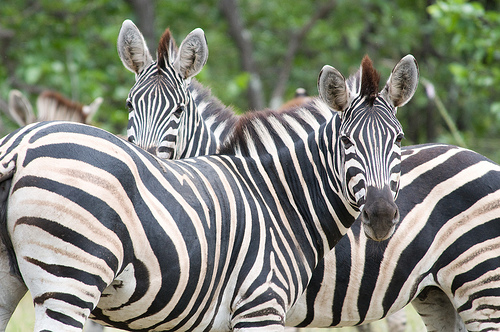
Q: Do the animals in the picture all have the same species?
A: Yes, all the animals are zebras.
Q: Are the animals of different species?
A: No, all the animals are zebras.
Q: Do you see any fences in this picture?
A: No, there are no fences.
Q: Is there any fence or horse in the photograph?
A: No, there are no fences or horses.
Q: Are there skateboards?
A: No, there are no skateboards.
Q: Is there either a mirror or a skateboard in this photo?
A: No, there are no skateboards or mirrors.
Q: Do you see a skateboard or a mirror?
A: No, there are no skateboards or mirrors.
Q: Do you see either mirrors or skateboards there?
A: No, there are no skateboards or mirrors.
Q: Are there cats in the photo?
A: No, there are no cats.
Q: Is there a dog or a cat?
A: No, there are no cats or dogs.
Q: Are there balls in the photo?
A: No, there are no balls.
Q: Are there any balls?
A: No, there are no balls.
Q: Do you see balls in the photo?
A: No, there are no balls.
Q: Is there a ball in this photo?
A: No, there are no balls.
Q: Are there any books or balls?
A: No, there are no balls or books.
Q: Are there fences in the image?
A: No, there are no fences.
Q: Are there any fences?
A: No, there are no fences.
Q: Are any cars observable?
A: No, there are no cars.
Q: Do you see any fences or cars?
A: No, there are no cars or fences.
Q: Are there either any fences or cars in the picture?
A: No, there are no cars or fences.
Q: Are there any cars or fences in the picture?
A: No, there are no cars or fences.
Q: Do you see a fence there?
A: No, there are no fences.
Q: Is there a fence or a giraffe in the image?
A: No, there are no fences or giraffes.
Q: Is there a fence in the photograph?
A: No, there are no fences.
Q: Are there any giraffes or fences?
A: No, there are no fences or giraffes.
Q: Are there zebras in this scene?
A: Yes, there is a zebra.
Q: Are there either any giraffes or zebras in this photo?
A: Yes, there is a zebra.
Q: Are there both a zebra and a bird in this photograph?
A: No, there is a zebra but no birds.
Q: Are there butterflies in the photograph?
A: No, there are no butterflies.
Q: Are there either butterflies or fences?
A: No, there are no butterflies or fences.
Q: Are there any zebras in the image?
A: Yes, there is a zebra.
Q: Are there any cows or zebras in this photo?
A: Yes, there is a zebra.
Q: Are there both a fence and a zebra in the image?
A: No, there is a zebra but no fences.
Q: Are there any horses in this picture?
A: No, there are no horses.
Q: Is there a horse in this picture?
A: No, there are no horses.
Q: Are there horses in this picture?
A: No, there are no horses.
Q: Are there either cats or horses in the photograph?
A: No, there are no horses or cats.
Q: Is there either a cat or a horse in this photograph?
A: No, there are no horses or cats.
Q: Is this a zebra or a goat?
A: This is a zebra.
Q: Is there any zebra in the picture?
A: Yes, there is a zebra.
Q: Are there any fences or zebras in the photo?
A: Yes, there is a zebra.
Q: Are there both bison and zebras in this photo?
A: No, there is a zebra but no bison.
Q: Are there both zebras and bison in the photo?
A: No, there is a zebra but no bison.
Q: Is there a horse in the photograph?
A: No, there are no horses.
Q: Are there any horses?
A: No, there are no horses.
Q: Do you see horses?
A: No, there are no horses.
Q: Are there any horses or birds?
A: No, there are no horses or birds.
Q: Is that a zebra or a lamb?
A: That is a zebra.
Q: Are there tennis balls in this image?
A: No, there are no tennis balls.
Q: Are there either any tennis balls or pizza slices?
A: No, there are no tennis balls or pizza slices.